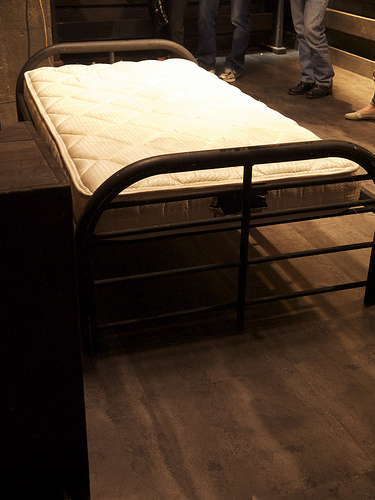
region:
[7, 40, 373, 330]
Small metal frame toddler bed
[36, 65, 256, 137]
White single mattress with quilting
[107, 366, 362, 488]
Light brown tile floor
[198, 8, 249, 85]
A person wearing jeans and tennis shoes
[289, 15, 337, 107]
Person wearing jeans and black boots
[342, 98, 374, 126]
Small beige slip on shoe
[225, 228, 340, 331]
Shadow from the frame of the bed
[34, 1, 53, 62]
Yellow cord hanging down the wall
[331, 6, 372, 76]
Wooden slats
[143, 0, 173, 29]
Small black purse with metal decorations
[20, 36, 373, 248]
a grey metal bed frame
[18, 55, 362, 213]
a mattress on a bed frame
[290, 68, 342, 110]
black shoes on a man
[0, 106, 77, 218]
a dark wooden chest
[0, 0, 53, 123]
a concrete block wall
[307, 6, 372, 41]
a horizontal wood board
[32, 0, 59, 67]
a cord running down a wall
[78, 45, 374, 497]
a dirty gray floor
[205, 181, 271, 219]
a tag on a mattress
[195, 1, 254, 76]
a pair of legs in blue jeans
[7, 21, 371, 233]
a bed with a mattress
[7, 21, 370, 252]
bed frame with mattress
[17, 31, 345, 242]
people standing around a bed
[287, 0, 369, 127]
a person's legs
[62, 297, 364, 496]
a cement floor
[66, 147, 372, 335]
a metal bed frame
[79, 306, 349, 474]
a concrete floor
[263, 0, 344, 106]
a person's leg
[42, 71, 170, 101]
top part of the mattress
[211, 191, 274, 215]
label on front of mattress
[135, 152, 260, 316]
part of bed railing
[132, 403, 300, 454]
a portion of the carpet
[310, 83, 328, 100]
black shoe on foot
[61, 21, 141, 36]
a shelf behind bed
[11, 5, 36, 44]
part of the wall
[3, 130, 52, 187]
top of the brown dresser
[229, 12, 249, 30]
the knee on person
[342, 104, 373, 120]
shoe on woman's foot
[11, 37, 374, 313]
a naked mattress on a metal bed frame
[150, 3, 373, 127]
the legs and feet of four people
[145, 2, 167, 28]
a black purse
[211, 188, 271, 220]
an old, tattered mattress tag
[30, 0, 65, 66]
yellow wire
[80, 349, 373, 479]
dirty and scuffed floor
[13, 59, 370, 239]
an uncovered mattress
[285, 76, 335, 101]
black mens shoes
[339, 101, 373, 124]
taupe womens flats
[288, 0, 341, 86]
men's blue jeans